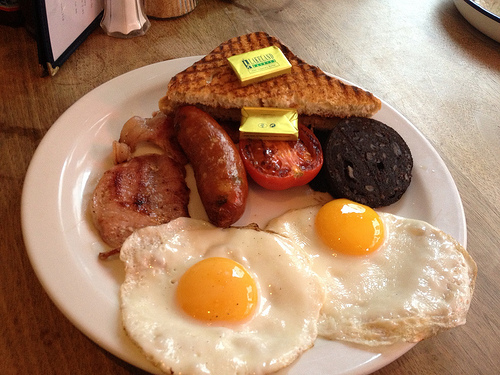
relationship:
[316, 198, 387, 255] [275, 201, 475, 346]
yellow yolk on egg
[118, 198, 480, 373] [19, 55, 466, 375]
eggs on plate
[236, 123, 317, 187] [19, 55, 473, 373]
tomato on plate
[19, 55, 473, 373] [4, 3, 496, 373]
plate sitting on top of table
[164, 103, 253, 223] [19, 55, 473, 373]
sausage on plate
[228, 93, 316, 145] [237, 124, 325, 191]
butter packet on top of tomato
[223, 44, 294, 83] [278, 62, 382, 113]
butter packet on top of bread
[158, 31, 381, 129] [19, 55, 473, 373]
bread on top of plate